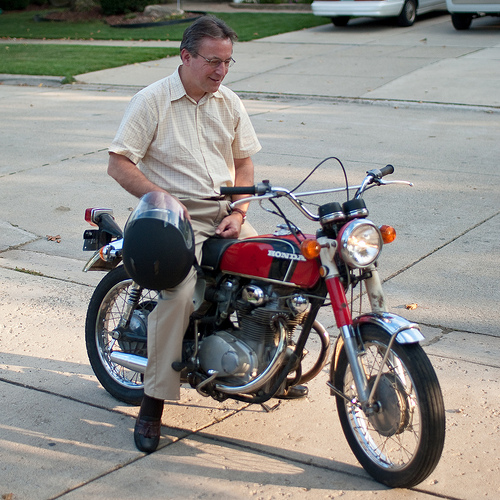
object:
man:
[113, 15, 274, 410]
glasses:
[192, 42, 240, 72]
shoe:
[112, 388, 170, 458]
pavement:
[3, 95, 489, 498]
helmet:
[115, 188, 196, 290]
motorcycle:
[82, 163, 442, 475]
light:
[381, 218, 394, 250]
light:
[299, 227, 319, 265]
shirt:
[106, 83, 265, 225]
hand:
[212, 201, 248, 237]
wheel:
[321, 318, 445, 483]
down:
[72, 160, 377, 320]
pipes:
[329, 286, 384, 411]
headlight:
[338, 218, 383, 270]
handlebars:
[215, 172, 276, 204]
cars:
[306, 0, 424, 24]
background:
[8, 1, 490, 87]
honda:
[253, 236, 316, 266]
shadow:
[12, 352, 467, 496]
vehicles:
[439, 0, 499, 32]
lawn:
[10, 39, 94, 67]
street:
[4, 50, 496, 251]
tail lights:
[83, 200, 118, 227]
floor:
[1, 264, 496, 499]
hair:
[169, 7, 237, 66]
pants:
[133, 174, 262, 409]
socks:
[134, 393, 166, 417]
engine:
[192, 288, 314, 407]